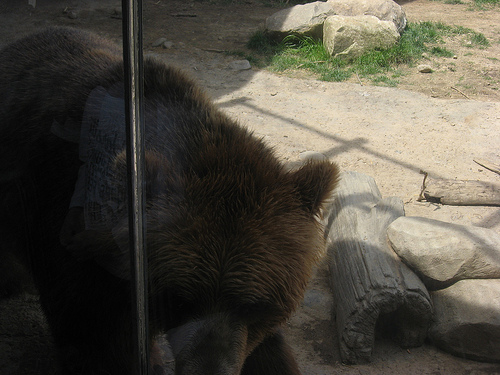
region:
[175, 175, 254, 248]
soft brown fur on a body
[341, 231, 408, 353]
an old hallow log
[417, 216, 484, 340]
large gray stones on the ground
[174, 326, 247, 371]
a long black snout on a head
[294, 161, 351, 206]
a brown furry ear on a head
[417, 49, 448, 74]
stone scattered on the ground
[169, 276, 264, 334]
eyes on a face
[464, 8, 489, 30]
a patch of dirt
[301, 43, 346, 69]
grass growing around a stone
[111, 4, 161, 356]
a black metal pole in front of the bear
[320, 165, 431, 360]
The large log in the bears enclosure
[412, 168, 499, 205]
The small log in the enclosure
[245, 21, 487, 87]
The grass surrounding the rocks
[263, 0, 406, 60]
The rocks surrounded by grass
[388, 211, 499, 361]
The rocks leaning against the log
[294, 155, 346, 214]
The bear's right ear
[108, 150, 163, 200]
The bear's left ear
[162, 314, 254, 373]
The snout of the bear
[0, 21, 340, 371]
The bear in the enclosure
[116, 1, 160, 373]
Where the glass panels meet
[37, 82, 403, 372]
There is a bear in the photo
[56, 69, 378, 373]
The bear is brown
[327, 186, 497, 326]
There are rocks in the background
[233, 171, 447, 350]
There is a bark in the background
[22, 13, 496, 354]
The photo was taken outside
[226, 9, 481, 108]
There is a patch of grass in the background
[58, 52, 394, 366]
There is a pole in front of the bear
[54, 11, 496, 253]
The photo was taken on a sunny day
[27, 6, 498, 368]
The photo was taken in the daytime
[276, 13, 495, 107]
There is a patch of grass around the rocks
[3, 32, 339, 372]
a brown bear in an enclosure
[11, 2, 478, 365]
a metal pane between windows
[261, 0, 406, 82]
two rocks in the background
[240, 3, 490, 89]
green grass growing around rocks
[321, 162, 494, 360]
tree truck next to rocks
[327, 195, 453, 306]
a rock on the tree trunk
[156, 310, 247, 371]
the bear's snout is black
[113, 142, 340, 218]
the bear's ears are brown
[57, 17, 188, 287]
a boy's reflection is in the window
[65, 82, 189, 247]
the boy is wearing a long sleeved t-shirt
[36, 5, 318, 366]
brown bear in zoo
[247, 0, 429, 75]
rocks surrounded by small patch of grass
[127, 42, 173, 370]
silver pole near brown bear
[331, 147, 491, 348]
logs and rocks on ground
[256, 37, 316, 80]
small patch of green grass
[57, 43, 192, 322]
reflection of person on glass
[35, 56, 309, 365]
large brown bear behind glass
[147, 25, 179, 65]
small rocks in dirt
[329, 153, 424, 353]
log with hole in it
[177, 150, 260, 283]
brown fur on bear